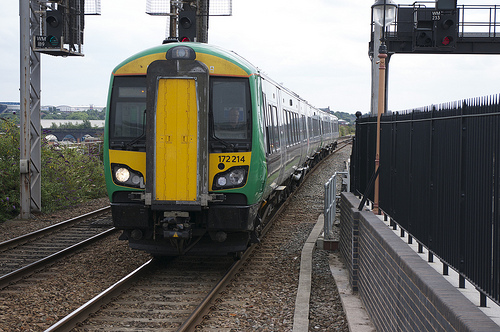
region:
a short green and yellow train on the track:
[103, 38, 348, 248]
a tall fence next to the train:
[346, 97, 498, 329]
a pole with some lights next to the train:
[368, 4, 498, 109]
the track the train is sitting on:
[42, 252, 229, 328]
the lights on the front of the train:
[113, 160, 250, 190]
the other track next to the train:
[1, 209, 106, 293]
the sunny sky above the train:
[0, 2, 498, 102]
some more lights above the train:
[168, 0, 203, 42]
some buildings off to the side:
[47, 125, 100, 154]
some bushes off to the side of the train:
[1, 121, 108, 209]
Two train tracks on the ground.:
[0, 250, 252, 330]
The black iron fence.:
[350, 90, 498, 199]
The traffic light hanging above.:
[428, 0, 457, 52]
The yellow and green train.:
[103, 43, 253, 265]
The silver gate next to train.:
[323, 163, 340, 249]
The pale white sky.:
[275, 0, 361, 76]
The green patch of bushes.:
[3, 128, 99, 215]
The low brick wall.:
[339, 188, 499, 329]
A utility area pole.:
[16, 0, 98, 220]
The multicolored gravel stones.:
[312, 266, 339, 330]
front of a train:
[120, 42, 262, 243]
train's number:
[184, 110, 269, 230]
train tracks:
[20, 243, 186, 329]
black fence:
[343, 113, 497, 220]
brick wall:
[341, 206, 403, 325]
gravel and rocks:
[256, 269, 321, 330]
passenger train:
[137, 78, 344, 174]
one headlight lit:
[117, 77, 282, 243]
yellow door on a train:
[160, 75, 200, 211]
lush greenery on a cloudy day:
[30, 107, 86, 202]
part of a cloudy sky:
[280, 9, 360, 67]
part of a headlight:
[116, 159, 139, 190]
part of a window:
[219, 99, 247, 147]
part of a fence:
[397, 173, 466, 251]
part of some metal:
[316, 190, 336, 236]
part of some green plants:
[25, 135, 74, 187]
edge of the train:
[248, 100, 270, 149]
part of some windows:
[270, 109, 307, 139]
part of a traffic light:
[163, 2, 196, 49]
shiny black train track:
[65, 272, 166, 307]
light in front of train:
[74, 149, 159, 205]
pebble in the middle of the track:
[47, 264, 84, 287]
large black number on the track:
[213, 142, 261, 170]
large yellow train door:
[163, 86, 195, 188]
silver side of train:
[265, 91, 329, 167]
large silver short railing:
[310, 159, 343, 239]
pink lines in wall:
[368, 261, 420, 320]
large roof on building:
[43, 114, 93, 142]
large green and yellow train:
[61, 11, 297, 258]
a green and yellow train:
[106, 39, 338, 254]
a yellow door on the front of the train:
[154, 80, 196, 201]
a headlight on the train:
[114, 165, 132, 181]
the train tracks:
[4, 201, 287, 329]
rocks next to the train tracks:
[257, 285, 293, 320]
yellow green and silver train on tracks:
[98, 41, 330, 258]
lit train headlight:
[110, 163, 131, 191]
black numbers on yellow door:
[215, 149, 257, 179]